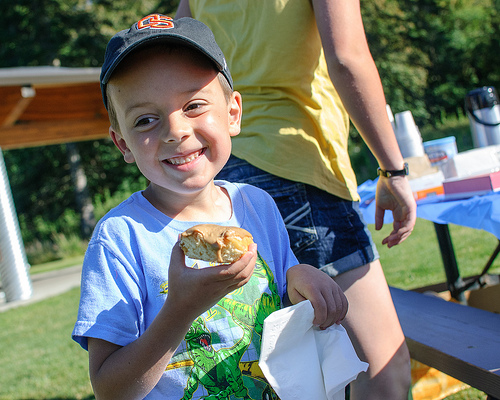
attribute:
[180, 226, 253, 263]
donut — half-eaten, eaten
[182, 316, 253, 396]
dinosaur — green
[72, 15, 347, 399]
boy — smiling, happy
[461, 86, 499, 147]
thermos — silver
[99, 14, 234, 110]
cap — blue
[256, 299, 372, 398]
napkin — white, clean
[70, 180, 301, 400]
shirt — blue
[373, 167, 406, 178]
band — black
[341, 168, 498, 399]
table — picnic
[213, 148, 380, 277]
shorts — blue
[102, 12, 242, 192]
head — smiling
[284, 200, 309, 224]
stripe — white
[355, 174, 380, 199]
water — blue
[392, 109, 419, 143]
cup — paper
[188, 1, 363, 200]
top — yellow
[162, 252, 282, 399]
design — green